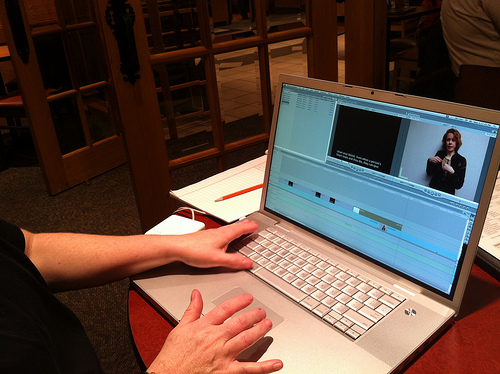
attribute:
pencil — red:
[214, 181, 263, 203]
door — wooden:
[100, 2, 345, 219]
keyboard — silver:
[245, 204, 415, 350]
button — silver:
[344, 302, 374, 329]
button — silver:
[389, 290, 409, 302]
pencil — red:
[216, 178, 267, 204]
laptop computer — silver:
[129, 72, 498, 370]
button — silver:
[333, 289, 354, 304]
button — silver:
[385, 285, 402, 307]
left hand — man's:
[19, 202, 303, 285]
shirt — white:
[437, 0, 499, 76]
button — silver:
[335, 312, 343, 325]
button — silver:
[330, 301, 351, 314]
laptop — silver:
[131, 72, 498, 372]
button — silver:
[380, 292, 400, 306]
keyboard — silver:
[272, 205, 451, 324]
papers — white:
[159, 154, 340, 249]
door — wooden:
[100, 4, 157, 99]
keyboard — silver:
[359, 305, 384, 325]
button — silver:
[350, 297, 363, 315]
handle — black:
[103, 0, 145, 100]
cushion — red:
[0, 82, 62, 111]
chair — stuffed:
[0, 82, 63, 116]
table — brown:
[128, 201, 499, 371]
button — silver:
[348, 308, 374, 327]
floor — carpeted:
[2, 158, 147, 368]